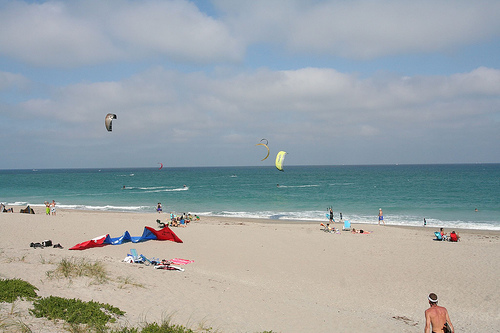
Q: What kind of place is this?
A: It is a beach.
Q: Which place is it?
A: It is a beach.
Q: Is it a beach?
A: Yes, it is a beach.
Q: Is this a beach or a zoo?
A: It is a beach.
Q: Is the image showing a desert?
A: No, the picture is showing a beach.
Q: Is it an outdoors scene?
A: Yes, it is outdoors.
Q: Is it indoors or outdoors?
A: It is outdoors.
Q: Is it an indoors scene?
A: No, it is outdoors.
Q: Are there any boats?
A: No, there are no boats.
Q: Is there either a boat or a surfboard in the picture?
A: No, there are no boats or surfboards.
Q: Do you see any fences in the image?
A: No, there are no fences.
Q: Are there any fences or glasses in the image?
A: No, there are no fences or glasses.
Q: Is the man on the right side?
A: Yes, the man is on the right of the image.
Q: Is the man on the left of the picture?
A: No, the man is on the right of the image.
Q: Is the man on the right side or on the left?
A: The man is on the right of the image.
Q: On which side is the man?
A: The man is on the right of the image.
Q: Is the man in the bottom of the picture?
A: Yes, the man is in the bottom of the image.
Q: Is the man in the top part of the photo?
A: No, the man is in the bottom of the image.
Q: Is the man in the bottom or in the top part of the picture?
A: The man is in the bottom of the image.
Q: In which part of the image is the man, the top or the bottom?
A: The man is in the bottom of the image.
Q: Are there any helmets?
A: No, there are no helmets.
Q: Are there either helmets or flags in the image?
A: No, there are no helmets or flags.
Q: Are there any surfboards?
A: No, there are no surfboards.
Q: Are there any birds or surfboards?
A: No, there are no surfboards or birds.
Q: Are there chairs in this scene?
A: Yes, there is a chair.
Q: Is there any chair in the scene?
A: Yes, there is a chair.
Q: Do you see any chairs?
A: Yes, there is a chair.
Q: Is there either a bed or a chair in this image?
A: Yes, there is a chair.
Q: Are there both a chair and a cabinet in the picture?
A: No, there is a chair but no cabinets.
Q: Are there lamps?
A: No, there are no lamps.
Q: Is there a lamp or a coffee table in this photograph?
A: No, there are no lamps or coffee tables.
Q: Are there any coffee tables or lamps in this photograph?
A: No, there are no lamps or coffee tables.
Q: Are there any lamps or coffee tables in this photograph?
A: No, there are no lamps or coffee tables.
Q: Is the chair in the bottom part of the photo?
A: Yes, the chair is in the bottom of the image.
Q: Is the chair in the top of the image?
A: No, the chair is in the bottom of the image.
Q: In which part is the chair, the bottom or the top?
A: The chair is in the bottom of the image.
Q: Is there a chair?
A: Yes, there is a chair.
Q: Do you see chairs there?
A: Yes, there is a chair.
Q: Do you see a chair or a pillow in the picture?
A: Yes, there is a chair.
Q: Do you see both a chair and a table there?
A: No, there is a chair but no tables.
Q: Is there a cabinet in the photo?
A: No, there are no cabinets.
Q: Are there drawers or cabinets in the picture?
A: No, there are no cabinets or drawers.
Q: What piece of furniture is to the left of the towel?
A: The piece of furniture is a chair.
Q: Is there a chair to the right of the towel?
A: No, the chair is to the left of the towel.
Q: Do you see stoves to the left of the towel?
A: No, there is a chair to the left of the towel.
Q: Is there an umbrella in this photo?
A: No, there are no umbrellas.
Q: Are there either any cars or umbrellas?
A: No, there are no umbrellas or cars.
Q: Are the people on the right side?
A: Yes, the people are on the right of the image.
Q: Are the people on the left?
A: No, the people are on the right of the image.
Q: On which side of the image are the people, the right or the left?
A: The people are on the right of the image.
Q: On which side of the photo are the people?
A: The people are on the right of the image.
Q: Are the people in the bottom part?
A: Yes, the people are in the bottom of the image.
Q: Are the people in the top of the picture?
A: No, the people are in the bottom of the image.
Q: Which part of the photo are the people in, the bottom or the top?
A: The people are in the bottom of the image.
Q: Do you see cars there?
A: No, there are no cars.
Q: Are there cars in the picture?
A: No, there are no cars.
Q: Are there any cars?
A: No, there are no cars.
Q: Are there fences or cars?
A: No, there are no cars or fences.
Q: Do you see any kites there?
A: Yes, there is a kite.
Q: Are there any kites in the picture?
A: Yes, there is a kite.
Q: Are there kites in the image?
A: Yes, there is a kite.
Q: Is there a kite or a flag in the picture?
A: Yes, there is a kite.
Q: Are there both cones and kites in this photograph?
A: No, there is a kite but no cones.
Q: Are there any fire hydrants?
A: No, there are no fire hydrants.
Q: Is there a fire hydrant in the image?
A: No, there are no fire hydrants.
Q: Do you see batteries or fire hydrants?
A: No, there are no fire hydrants or batteries.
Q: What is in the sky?
A: The kite is in the sky.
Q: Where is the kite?
A: The kite is in the sky.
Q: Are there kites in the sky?
A: Yes, there is a kite in the sky.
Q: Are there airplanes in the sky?
A: No, there is a kite in the sky.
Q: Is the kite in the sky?
A: Yes, the kite is in the sky.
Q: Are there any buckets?
A: No, there are no buckets.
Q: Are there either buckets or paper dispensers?
A: No, there are no buckets or paper dispensers.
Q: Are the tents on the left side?
A: Yes, the tents are on the left of the image.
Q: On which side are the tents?
A: The tents are on the left of the image.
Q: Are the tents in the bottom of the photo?
A: Yes, the tents are in the bottom of the image.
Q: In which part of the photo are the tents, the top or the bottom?
A: The tents are in the bottom of the image.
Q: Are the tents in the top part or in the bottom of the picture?
A: The tents are in the bottom of the image.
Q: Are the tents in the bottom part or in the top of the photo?
A: The tents are in the bottom of the image.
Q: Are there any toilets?
A: No, there are no toilets.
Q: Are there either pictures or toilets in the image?
A: No, there are no toilets or pictures.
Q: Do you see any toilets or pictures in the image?
A: No, there are no toilets or pictures.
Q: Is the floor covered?
A: Yes, the floor is covered.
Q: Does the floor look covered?
A: Yes, the floor is covered.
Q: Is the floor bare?
A: No, the floor is covered.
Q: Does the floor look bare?
A: No, the floor is covered.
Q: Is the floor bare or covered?
A: The floor is covered.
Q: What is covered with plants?
A: The floor is covered with plants.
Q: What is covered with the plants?
A: The floor is covered with plants.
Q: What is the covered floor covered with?
A: The floor is covered with plants.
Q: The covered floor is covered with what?
A: The floor is covered with plants.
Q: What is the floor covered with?
A: The floor is covered with plants.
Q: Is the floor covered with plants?
A: Yes, the floor is covered with plants.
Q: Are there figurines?
A: No, there are no figurines.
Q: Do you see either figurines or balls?
A: No, there are no figurines or balls.